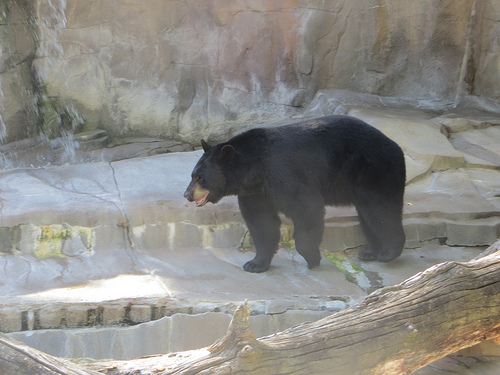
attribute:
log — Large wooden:
[144, 254, 483, 364]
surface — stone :
[164, 270, 367, 302]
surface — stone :
[147, 254, 249, 304]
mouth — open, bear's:
[184, 191, 204, 212]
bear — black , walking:
[168, 115, 423, 275]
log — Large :
[191, 244, 424, 373]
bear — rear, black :
[176, 120, 413, 269]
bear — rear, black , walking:
[181, 112, 418, 266]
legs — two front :
[226, 200, 324, 280]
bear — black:
[159, 115, 409, 270]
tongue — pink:
[184, 186, 227, 216]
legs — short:
[224, 190, 439, 260]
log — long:
[214, 227, 494, 365]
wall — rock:
[18, 14, 452, 166]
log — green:
[353, 284, 493, 370]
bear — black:
[146, 111, 426, 275]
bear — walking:
[169, 129, 439, 280]